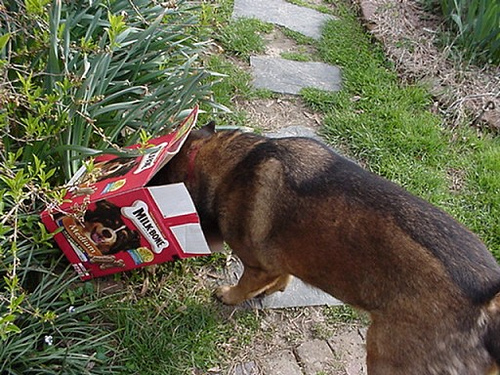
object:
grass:
[278, 0, 499, 267]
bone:
[117, 198, 171, 256]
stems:
[93, 85, 149, 110]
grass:
[359, 0, 499, 138]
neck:
[185, 128, 253, 220]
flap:
[139, 182, 212, 262]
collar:
[181, 146, 200, 195]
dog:
[166, 118, 500, 374]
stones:
[251, 347, 305, 374]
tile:
[229, 0, 337, 48]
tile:
[246, 55, 344, 103]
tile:
[261, 123, 323, 140]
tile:
[254, 274, 346, 311]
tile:
[293, 337, 345, 374]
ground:
[121, 1, 498, 374]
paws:
[213, 285, 239, 307]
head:
[78, 198, 143, 257]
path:
[215, 0, 381, 315]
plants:
[0, 0, 237, 194]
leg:
[231, 262, 280, 299]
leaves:
[43, 165, 58, 182]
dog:
[47, 198, 144, 265]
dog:
[78, 152, 139, 184]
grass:
[0, 0, 275, 374]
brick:
[324, 326, 376, 373]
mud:
[252, 305, 328, 355]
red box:
[37, 101, 225, 282]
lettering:
[154, 240, 166, 248]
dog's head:
[148, 118, 216, 233]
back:
[246, 135, 499, 299]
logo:
[120, 198, 169, 256]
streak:
[254, 135, 499, 308]